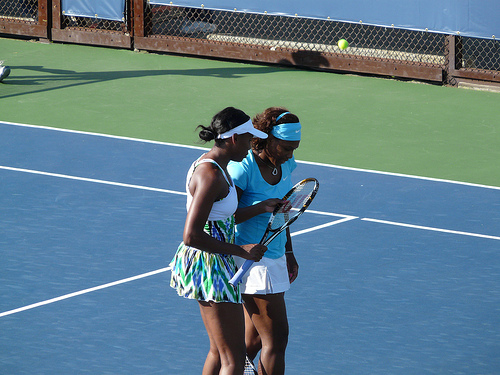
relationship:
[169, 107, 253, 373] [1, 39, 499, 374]
tennis player on court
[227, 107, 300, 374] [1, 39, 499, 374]
tennis player on court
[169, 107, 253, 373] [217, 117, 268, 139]
tennis player wearing visor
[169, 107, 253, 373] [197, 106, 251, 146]
tennis player with hair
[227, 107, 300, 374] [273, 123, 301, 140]
tennis player wearing band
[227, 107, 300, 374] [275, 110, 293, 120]
tennis player wearing band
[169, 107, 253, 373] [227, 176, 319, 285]
tennis player holding racket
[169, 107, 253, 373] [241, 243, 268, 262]
tennis player with hand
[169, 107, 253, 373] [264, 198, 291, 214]
tennis player with hand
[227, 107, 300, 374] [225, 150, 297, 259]
tennis player wearing shirt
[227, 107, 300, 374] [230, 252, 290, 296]
tennis player wearing skirt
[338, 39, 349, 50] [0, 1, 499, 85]
ball by fence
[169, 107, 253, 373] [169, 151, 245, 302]
tennis player wearing tennis dress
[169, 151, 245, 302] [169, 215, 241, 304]
tennis dress with designs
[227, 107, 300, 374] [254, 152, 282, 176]
tennis player wearing necklace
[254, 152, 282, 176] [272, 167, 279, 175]
necklace with pendant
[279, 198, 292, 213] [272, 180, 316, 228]
fingers under strings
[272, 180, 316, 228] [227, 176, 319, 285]
strings of racket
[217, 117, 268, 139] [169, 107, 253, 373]
visor on tennis player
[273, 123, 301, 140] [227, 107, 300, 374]
band on tennis player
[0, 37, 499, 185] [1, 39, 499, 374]
out-of-bounds on court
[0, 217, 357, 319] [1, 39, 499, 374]
singles line on court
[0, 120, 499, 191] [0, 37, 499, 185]
line for out-of-bounds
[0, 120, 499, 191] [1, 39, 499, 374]
line on court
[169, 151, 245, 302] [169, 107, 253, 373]
tennis dress on tennis player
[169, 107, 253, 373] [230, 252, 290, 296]
tennis player in skirt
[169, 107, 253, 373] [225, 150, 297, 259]
tennis player in shirt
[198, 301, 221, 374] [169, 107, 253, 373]
leg of tennis player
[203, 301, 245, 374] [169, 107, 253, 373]
leg of tennis player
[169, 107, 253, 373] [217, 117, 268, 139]
tennis player in visor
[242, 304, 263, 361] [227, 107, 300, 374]
leg of tennis player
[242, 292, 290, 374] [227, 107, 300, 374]
leg of tennis player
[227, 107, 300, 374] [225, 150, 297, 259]
tennis player in shirt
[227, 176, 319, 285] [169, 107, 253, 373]
racket of tennis player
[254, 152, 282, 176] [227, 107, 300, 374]
necklace of tennis player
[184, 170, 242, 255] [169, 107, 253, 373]
arm of tennis player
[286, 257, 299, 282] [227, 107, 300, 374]
hand of tennis player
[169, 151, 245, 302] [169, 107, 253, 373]
tennis dress of tennis player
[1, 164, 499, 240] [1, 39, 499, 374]
line on court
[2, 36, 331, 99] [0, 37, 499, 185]
shadow on out-of-bounds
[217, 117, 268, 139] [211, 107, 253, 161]
visor on head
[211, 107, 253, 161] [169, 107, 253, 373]
head of tennis player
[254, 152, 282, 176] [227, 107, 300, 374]
necklace on tennis player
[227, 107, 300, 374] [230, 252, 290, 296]
tennis player in skirt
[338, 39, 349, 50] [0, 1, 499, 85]
ball in fence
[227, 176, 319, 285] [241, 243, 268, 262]
racket in hand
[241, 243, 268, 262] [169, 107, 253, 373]
hand of tennis player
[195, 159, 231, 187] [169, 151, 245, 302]
strap on tennis dress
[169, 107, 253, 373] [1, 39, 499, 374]
tennis player talking on court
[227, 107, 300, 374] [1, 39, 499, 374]
tennis player talking on court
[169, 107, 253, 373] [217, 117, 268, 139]
tennis player wears visor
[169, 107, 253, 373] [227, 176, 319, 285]
tennis player holds racket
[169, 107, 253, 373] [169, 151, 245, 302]
tennis player wears tennis dress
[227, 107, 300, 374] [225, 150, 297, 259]
tennis player wears shirt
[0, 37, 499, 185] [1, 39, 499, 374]
out-of-bounds of court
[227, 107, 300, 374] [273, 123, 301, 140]
tennis player wears band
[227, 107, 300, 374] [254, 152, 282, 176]
tennis player wears necklace